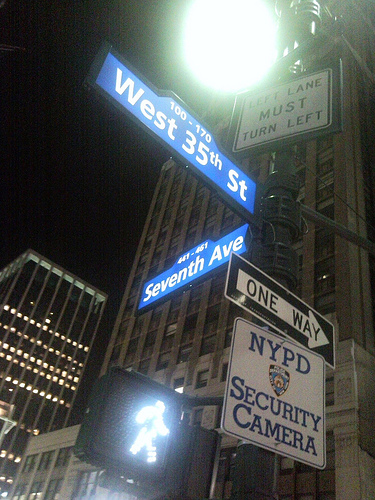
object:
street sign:
[134, 220, 251, 317]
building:
[0, 242, 108, 500]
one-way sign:
[222, 250, 338, 370]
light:
[173, 0, 284, 102]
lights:
[4, 305, 10, 312]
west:
[115, 68, 178, 140]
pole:
[299, 202, 375, 252]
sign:
[220, 315, 327, 470]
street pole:
[202, 148, 278, 500]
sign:
[77, 365, 185, 495]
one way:
[246, 273, 322, 341]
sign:
[84, 40, 259, 217]